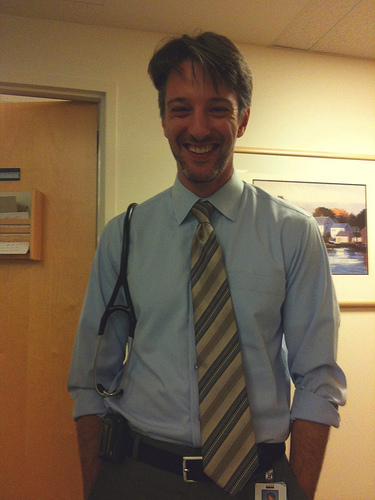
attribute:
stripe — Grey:
[197, 256, 259, 488]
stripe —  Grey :
[184, 228, 201, 257]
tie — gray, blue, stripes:
[194, 194, 266, 498]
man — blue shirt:
[66, 24, 353, 496]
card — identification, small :
[251, 471, 298, 498]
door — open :
[1, 76, 97, 497]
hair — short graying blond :
[203, 38, 240, 87]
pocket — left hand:
[245, 441, 303, 492]